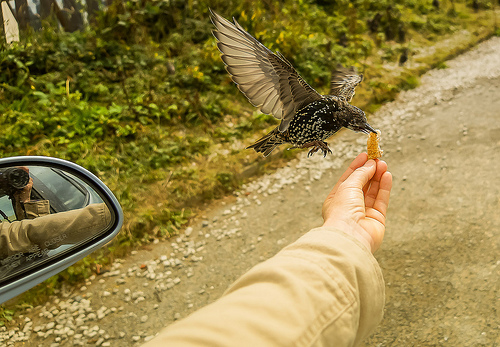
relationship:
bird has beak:
[202, 3, 386, 159] [364, 123, 384, 138]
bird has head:
[202, 3, 386, 159] [340, 97, 365, 123]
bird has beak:
[202, 3, 386, 159] [362, 116, 379, 138]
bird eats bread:
[202, 3, 386, 159] [365, 128, 382, 163]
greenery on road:
[0, 0, 490, 180] [172, 94, 480, 315]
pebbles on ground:
[48, 283, 116, 336] [400, 73, 450, 113]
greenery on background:
[0, 0, 490, 180] [6, 7, 494, 35]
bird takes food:
[206, 3, 386, 162] [365, 128, 389, 160]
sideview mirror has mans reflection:
[1, 147, 126, 307] [0, 151, 127, 305]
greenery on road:
[43, 0, 491, 180] [116, 73, 494, 344]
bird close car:
[202, 3, 386, 159] [5, 147, 144, 345]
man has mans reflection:
[9, 165, 60, 247] [0, 162, 112, 266]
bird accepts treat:
[206, 3, 386, 162] [362, 125, 386, 162]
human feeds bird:
[131, 138, 413, 345] [206, 3, 386, 162]